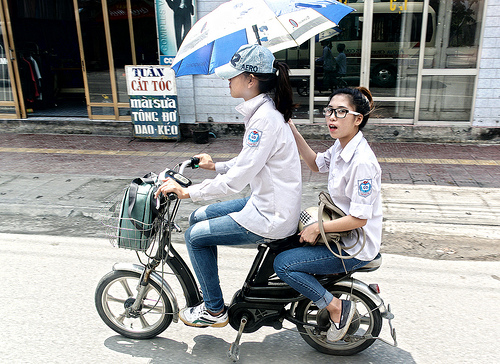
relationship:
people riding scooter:
[174, 37, 390, 348] [93, 160, 404, 356]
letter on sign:
[135, 97, 177, 137] [120, 59, 185, 149]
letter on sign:
[145, 63, 157, 79] [109, 50, 186, 147]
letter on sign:
[153, 65, 165, 77] [109, 50, 186, 147]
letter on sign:
[135, 97, 177, 137] [109, 50, 186, 147]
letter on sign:
[128, 110, 138, 124] [109, 50, 186, 147]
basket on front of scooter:
[108, 212, 169, 254] [93, 160, 404, 356]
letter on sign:
[135, 84, 154, 115] [122, 62, 180, 140]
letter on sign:
[131, 108, 158, 121] [122, 62, 180, 140]